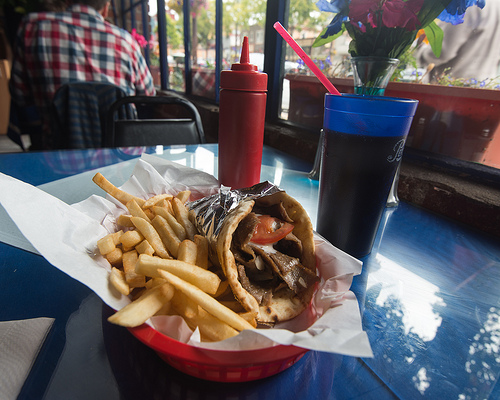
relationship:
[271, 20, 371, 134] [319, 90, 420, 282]
drinking straw in cup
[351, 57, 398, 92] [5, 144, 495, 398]
flower vase on table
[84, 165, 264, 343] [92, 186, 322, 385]
fries in container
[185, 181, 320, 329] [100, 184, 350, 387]
gyro in container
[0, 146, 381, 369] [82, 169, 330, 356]
paper under food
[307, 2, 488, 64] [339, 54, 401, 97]
flowers in vase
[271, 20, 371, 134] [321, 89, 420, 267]
drinking straw in cup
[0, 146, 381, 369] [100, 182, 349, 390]
paper in basket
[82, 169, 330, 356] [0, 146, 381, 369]
food in paper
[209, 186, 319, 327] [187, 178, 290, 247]
tortilla wrapped in foil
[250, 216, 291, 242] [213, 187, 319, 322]
sliced tomato in bread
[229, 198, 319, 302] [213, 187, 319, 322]
meat in bread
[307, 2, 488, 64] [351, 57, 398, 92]
flowers in flower vase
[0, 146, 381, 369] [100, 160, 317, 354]
paper under food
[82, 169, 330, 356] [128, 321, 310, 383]
food in basket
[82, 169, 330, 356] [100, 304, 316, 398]
food in plate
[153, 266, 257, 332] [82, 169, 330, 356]
french fry lying in food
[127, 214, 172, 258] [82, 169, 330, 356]
french fry lying in food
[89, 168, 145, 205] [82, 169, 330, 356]
french fry lying in food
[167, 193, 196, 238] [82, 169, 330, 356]
french fry lying in food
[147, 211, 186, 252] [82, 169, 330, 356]
french fry lying in food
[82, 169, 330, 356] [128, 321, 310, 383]
food served in basket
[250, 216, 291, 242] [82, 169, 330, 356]
sliced tomato served in food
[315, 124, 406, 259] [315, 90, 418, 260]
soda served in cup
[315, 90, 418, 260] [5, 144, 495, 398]
cup sitting on top of table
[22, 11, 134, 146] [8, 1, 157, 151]
back belonging to man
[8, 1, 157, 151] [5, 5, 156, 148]
man wearing shirt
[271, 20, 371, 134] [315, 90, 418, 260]
drinking straw sticking out of cup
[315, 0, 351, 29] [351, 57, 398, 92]
flower standing in flower vase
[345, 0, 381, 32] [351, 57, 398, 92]
flower standing in flower vase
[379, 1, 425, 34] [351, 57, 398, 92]
flower standing in flower vase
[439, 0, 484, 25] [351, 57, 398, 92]
flower standing in flower vase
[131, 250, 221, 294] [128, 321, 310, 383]
fry lying inside basket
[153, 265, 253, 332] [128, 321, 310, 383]
fry lying inside basket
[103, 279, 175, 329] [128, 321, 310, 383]
fry lying inside basket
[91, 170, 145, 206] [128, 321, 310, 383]
fry lying inside basket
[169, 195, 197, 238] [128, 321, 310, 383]
fry lying inside basket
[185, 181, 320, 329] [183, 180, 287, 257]
gyro wrapped in tin foil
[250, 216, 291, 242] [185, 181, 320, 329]
sliced tomato topping gyro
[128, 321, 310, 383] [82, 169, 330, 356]
basket holding food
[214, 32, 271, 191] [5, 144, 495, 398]
bottle standing on top of table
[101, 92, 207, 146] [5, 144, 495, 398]
chair sitting in front of table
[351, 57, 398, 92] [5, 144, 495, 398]
flower vase standing on top of table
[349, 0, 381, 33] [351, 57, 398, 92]
flower standing in flower vase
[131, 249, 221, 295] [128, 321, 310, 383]
french fry lying inside basket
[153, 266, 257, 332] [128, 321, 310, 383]
french fry lying inside basket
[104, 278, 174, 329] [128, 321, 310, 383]
french fry lying inside basket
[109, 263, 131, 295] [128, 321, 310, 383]
french fry lying inside basket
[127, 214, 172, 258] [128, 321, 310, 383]
french fry lying inside basket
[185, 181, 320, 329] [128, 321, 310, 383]
gyro lying inside basket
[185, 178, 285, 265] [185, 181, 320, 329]
foil wrapped around gyro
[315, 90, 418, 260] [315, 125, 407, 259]
cup containing pepsi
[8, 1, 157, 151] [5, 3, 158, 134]
man in a shirt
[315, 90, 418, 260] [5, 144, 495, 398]
cup on top of table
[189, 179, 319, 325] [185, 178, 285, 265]
wrap in foil